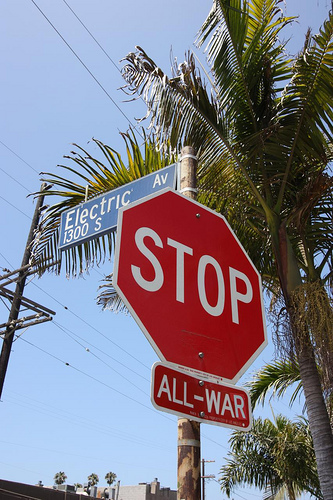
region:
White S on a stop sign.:
[130, 226, 163, 293]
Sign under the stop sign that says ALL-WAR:
[149, 360, 252, 432]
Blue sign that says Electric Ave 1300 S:
[55, 161, 185, 251]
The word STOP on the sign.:
[131, 225, 253, 324]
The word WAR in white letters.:
[204, 388, 245, 419]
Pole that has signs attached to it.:
[176, 413, 199, 499]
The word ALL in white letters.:
[157, 374, 194, 406]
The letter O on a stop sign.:
[195, 253, 224, 316]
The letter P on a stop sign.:
[227, 264, 251, 323]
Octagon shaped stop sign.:
[111, 186, 267, 385]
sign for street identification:
[57, 162, 179, 250]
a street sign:
[56, 159, 177, 250]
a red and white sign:
[114, 183, 265, 381]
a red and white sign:
[146, 364, 252, 428]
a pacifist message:
[115, 189, 265, 431]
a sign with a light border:
[114, 188, 268, 382]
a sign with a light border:
[150, 362, 252, 432]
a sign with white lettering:
[146, 362, 249, 431]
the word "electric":
[59, 182, 130, 230]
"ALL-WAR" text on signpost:
[155, 369, 248, 420]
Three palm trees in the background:
[47, 469, 116, 486]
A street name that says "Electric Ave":
[55, 161, 182, 255]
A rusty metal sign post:
[174, 414, 200, 499]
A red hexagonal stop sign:
[109, 186, 271, 379]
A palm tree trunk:
[282, 257, 331, 499]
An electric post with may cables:
[0, 177, 56, 399]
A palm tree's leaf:
[278, 0, 330, 210]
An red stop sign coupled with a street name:
[54, 144, 265, 496]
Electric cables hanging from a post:
[22, 277, 129, 401]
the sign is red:
[123, 206, 265, 378]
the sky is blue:
[9, 368, 163, 480]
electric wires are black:
[47, 304, 144, 400]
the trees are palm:
[149, 101, 327, 252]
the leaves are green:
[233, 427, 310, 480]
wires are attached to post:
[0, 236, 62, 354]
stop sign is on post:
[175, 415, 195, 496]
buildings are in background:
[57, 478, 170, 491]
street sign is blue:
[59, 170, 186, 232]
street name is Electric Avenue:
[66, 186, 155, 227]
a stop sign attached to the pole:
[114, 189, 269, 379]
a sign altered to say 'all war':
[144, 364, 251, 430]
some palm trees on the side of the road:
[59, 2, 330, 497]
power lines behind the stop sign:
[18, 277, 153, 417]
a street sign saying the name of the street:
[51, 162, 180, 240]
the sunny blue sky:
[4, 3, 174, 474]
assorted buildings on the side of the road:
[0, 467, 172, 498]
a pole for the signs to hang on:
[174, 416, 205, 498]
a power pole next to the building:
[197, 456, 213, 498]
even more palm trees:
[47, 469, 115, 485]